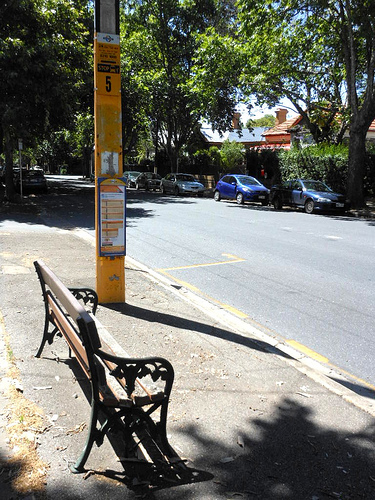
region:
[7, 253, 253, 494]
bench on a sidewalk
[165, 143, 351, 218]
cars parked on side of street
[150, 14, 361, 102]
sun shining on trees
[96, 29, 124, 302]
yellow sign says 5 on there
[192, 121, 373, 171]
houses behind trees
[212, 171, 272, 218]
2 door car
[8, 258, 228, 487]
No one is sitting on the bench.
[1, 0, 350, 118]
All the leaves are on the tree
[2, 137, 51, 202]
sign behind car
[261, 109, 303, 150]
orange roof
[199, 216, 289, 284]
this is a road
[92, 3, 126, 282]
this is a pole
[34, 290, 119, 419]
this is a bench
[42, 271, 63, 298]
the bench is wooden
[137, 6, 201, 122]
this is a tree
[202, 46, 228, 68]
the tree has green leaves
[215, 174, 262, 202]
this is a car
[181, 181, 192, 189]
the car is white in color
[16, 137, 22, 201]
this is a signpost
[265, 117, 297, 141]
this is a building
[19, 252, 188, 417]
Brown bench on gravel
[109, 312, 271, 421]
Gray cement sidewalk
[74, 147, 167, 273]
Yellow sign on a sidewalk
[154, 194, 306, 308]
Gray paved road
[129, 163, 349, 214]
Cars parked on the street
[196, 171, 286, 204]
Blue car on the street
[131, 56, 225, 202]
Tree by a road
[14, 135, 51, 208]
Street sign on a pole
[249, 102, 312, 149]
House by trees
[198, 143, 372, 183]
Bushes along a sidewalk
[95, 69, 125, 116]
black number five on yellow pole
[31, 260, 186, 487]
park bench on sidewalk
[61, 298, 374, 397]
shadow of the pole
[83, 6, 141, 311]
tall bright yellow pole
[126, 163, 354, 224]
cars parked along the street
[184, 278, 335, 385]
curb painted yellow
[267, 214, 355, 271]
center line of a street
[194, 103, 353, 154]
rooves of several houses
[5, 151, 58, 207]
the back of a parked vehicle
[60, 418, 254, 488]
small debris on sidewalk next to bench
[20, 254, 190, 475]
a wood and black metal bench on a sidewalk along the street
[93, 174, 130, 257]
instructions printed on a sign at a bus stop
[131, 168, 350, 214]
a long line of cars parked on the side of the street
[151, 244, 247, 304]
yellow lines painted in the road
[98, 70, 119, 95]
a black number 5 on the bus stop pole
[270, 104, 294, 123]
a chimney on a house that is nearby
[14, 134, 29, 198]
a sign on the side of the road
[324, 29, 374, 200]
a large brown trunk of a tree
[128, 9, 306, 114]
many green leaves of the trees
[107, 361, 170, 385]
the ornate design of the metal on the bench